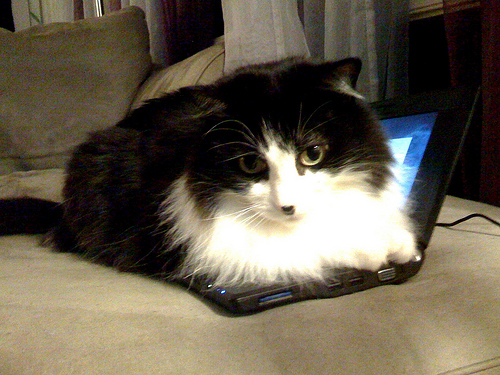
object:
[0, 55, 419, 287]
cat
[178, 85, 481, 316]
laptop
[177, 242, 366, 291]
keys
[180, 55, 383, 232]
head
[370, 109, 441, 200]
laptop screen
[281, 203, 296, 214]
nose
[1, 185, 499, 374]
chair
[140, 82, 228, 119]
ear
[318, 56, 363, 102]
ear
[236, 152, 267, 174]
eye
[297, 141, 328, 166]
eye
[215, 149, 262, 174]
whisker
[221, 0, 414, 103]
curtain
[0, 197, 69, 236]
tail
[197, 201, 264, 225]
whisker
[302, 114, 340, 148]
whisker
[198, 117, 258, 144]
whisker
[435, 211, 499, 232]
cord